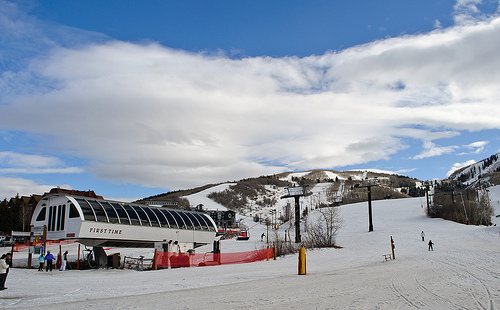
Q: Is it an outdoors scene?
A: Yes, it is outdoors.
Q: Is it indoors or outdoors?
A: It is outdoors.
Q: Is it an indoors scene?
A: No, it is outdoors.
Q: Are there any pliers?
A: No, there are no pliers.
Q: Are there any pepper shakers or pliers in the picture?
A: No, there are no pliers or pepper shakers.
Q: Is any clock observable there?
A: No, there are no clocks.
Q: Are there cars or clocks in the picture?
A: No, there are no clocks or cars.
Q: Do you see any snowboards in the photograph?
A: No, there are no snowboards.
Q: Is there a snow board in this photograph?
A: No, there are no snowboards.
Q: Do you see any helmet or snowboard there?
A: No, there are no snowboards or helmets.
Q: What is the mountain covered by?
A: The mountain is covered by the snow.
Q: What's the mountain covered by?
A: The mountain is covered by the snow.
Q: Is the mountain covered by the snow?
A: Yes, the mountain is covered by the snow.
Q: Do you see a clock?
A: No, there are no clocks.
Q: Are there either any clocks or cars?
A: No, there are no clocks or cars.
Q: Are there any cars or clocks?
A: No, there are no clocks or cars.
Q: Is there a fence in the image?
A: Yes, there is a fence.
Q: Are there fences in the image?
A: Yes, there is a fence.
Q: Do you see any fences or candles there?
A: Yes, there is a fence.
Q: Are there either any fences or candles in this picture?
A: Yes, there is a fence.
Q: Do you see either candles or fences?
A: Yes, there is a fence.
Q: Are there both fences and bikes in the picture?
A: No, there is a fence but no bikes.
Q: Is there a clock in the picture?
A: No, there are no clocks.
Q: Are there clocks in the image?
A: No, there are no clocks.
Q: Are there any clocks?
A: No, there are no clocks.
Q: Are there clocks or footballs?
A: No, there are no clocks or footballs.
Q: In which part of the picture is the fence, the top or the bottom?
A: The fence is in the bottom of the image.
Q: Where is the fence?
A: The fence is on the snow.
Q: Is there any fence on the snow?
A: Yes, there is a fence on the snow.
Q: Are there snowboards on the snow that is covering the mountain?
A: No, there is a fence on the snow.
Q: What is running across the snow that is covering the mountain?
A: The fence is running across the snow.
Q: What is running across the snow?
A: The fence is running across the snow.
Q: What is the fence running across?
A: The fence is running across the snow.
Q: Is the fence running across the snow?
A: Yes, the fence is running across the snow.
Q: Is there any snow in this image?
A: Yes, there is snow.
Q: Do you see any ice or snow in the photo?
A: Yes, there is snow.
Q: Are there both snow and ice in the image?
A: No, there is snow but no ice.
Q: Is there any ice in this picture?
A: No, there is no ice.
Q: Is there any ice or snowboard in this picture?
A: No, there are no ice or snowboards.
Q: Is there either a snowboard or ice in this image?
A: No, there are no ice or snowboards.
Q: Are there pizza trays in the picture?
A: No, there are no pizza trays.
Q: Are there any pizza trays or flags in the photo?
A: No, there are no pizza trays or flags.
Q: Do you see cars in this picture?
A: No, there are no cars.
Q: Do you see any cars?
A: No, there are no cars.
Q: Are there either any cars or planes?
A: No, there are no cars or planes.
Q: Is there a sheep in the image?
A: No, there is no sheep.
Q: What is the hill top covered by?
A: The hill top is covered by the snow.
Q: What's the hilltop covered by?
A: The hill top is covered by the snow.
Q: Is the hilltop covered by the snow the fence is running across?
A: Yes, the hilltop is covered by the snow.